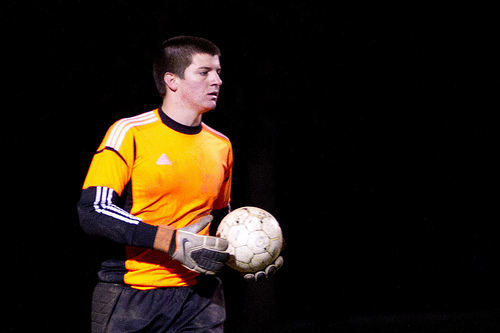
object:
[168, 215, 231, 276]
hand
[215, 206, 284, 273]
ball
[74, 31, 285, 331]
goalie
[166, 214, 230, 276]
glove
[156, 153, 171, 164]
logo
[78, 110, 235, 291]
shirt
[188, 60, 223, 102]
face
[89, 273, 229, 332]
shorts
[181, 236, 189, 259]
logo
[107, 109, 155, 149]
stripes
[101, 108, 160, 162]
shoulder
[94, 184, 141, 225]
stripes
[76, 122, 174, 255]
arm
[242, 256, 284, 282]
glove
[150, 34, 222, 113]
head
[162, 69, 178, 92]
ear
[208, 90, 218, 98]
mouth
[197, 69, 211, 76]
eye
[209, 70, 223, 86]
nose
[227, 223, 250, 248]
hexagon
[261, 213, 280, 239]
hexagon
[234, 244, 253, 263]
hexagon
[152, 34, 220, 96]
hair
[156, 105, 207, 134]
trim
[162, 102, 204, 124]
neck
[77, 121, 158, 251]
sleeve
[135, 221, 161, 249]
cuff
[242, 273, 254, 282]
finger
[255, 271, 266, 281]
finger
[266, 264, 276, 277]
finger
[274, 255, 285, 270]
finger